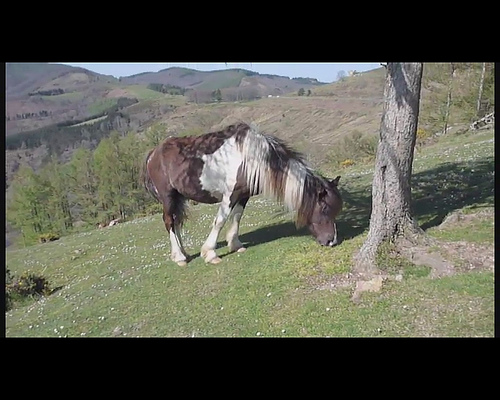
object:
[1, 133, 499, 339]
grass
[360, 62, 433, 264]
trunk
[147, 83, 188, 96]
trees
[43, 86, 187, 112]
hillside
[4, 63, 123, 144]
hills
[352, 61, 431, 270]
tree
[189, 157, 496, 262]
shadow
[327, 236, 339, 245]
nose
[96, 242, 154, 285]
flowers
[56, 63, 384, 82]
sky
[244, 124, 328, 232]
mane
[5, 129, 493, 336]
hill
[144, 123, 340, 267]
pony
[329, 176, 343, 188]
ears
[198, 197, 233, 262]
legs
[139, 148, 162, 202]
tail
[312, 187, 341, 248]
face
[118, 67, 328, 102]
mountains